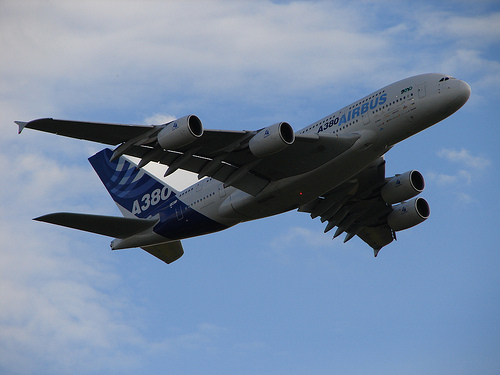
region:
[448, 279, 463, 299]
part of the sky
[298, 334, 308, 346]
edge of a sky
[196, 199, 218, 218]
part of a plane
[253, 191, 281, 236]
edge of a plane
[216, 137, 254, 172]
part of an engine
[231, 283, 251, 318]
edge of a cloud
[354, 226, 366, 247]
part of a plane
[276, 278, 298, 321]
part of the sky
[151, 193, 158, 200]
edge of a plane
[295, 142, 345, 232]
tip of a plane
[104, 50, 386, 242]
white airliner in sky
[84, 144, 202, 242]
blue tail of jet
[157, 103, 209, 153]
large engine under wing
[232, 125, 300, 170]
large engine under wing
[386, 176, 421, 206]
large engine under wing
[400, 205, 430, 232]
large engine under wing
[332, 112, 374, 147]
row of passenger windows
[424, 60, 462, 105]
cockpit windows on front of plane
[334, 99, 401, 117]
airbus written on side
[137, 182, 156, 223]
a380 written on tail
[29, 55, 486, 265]
airplane in air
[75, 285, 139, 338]
white clouds in blue sky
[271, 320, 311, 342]
white clouds in blue sky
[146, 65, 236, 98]
white clouds in blue sky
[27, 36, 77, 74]
white clouds in blue sky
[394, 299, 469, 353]
white clouds in blue sky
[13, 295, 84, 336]
white clouds in blue sky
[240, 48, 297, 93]
white clouds in blue sky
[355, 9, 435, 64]
white clouds in blue sky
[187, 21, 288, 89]
white clouds in blue sky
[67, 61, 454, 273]
plane is in air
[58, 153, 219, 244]
white and blue tail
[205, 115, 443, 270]
white and blue engines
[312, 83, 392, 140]
blue name on plane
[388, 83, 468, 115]
white nose on plane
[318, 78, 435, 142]
long row of windows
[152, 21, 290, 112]
sky is white and blue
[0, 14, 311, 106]
puffy clouds in sky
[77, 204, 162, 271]
white tail on plane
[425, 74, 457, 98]
windows on front of plane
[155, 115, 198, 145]
the white and blue engine of the plane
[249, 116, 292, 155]
the white and blue engine of the plane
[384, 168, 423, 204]
the white and blue engine of the plane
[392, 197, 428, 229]
the white and blue engine of the plane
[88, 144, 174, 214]
the light blue and dark blue tail of the plane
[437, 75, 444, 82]
the small window of the plane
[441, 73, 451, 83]
the small window of the plane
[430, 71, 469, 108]
the rounded white nose of the plane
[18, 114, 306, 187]
the wing of the plane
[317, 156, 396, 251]
the wing of the plane